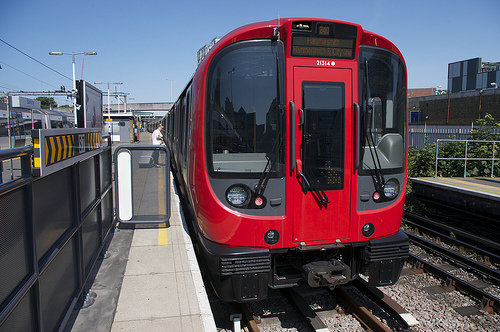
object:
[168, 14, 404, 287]
train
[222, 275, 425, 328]
tracks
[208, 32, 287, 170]
windshield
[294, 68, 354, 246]
door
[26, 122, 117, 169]
sign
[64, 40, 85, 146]
utility pole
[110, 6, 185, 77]
sky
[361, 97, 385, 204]
windshield wiper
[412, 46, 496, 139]
building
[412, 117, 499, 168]
shrubbery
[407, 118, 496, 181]
fence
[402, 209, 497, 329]
train tracks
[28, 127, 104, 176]
sign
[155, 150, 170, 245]
paint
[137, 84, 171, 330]
walkway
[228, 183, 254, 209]
light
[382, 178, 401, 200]
light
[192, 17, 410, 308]
front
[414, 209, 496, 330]
rail lines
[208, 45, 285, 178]
window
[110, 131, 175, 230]
security cate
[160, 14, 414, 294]
commuter train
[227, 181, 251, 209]
headlight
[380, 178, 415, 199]
headlight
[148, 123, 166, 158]
person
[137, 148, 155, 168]
bag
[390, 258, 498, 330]
base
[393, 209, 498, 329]
tracks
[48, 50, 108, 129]
light pole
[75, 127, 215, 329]
sidewalk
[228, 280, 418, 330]
train tracks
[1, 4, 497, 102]
sky